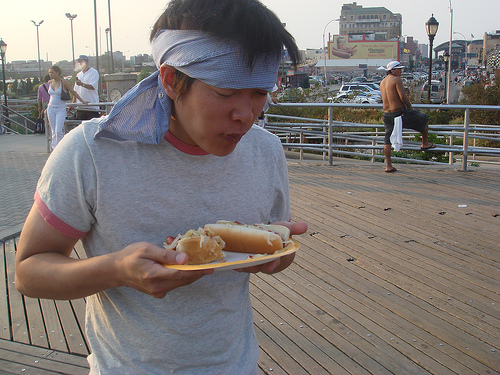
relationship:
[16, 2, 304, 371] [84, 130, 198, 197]
man has shirt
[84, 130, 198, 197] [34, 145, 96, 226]
shirt has sleeve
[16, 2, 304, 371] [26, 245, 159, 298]
man has arm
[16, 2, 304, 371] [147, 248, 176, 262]
man has thumb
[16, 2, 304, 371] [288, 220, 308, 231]
man has thumb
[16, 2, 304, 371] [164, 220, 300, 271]
man has food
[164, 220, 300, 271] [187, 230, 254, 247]
food has food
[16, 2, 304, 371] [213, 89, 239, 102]
man has eye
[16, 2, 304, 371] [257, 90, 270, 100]
man has eye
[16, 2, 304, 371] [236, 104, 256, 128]
man has nose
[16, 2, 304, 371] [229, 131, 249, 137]
man has lip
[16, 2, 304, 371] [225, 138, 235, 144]
man has lip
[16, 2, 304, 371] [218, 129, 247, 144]
man has mouth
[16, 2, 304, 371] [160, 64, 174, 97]
man has ear